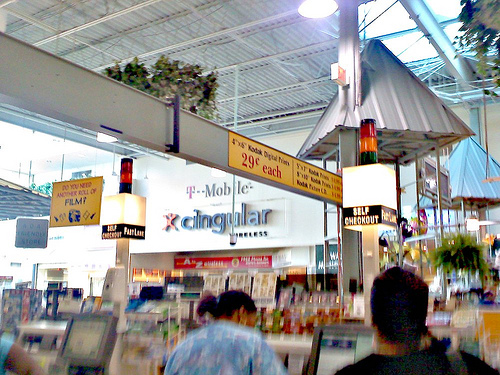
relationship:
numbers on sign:
[239, 153, 287, 185] [221, 122, 347, 202]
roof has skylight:
[3, 4, 500, 114] [356, 0, 500, 92]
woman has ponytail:
[162, 285, 283, 372] [197, 288, 221, 321]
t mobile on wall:
[183, 177, 249, 204] [150, 174, 351, 251]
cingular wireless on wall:
[183, 202, 297, 240] [150, 174, 351, 251]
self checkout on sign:
[340, 205, 391, 224] [342, 190, 399, 227]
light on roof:
[294, 0, 339, 29] [0, 0, 500, 162]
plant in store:
[431, 226, 494, 274] [375, 130, 496, 374]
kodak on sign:
[248, 145, 268, 153] [221, 122, 347, 202]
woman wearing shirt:
[162, 285, 283, 372] [165, 326, 291, 372]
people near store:
[158, 263, 496, 365] [375, 130, 496, 374]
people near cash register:
[158, 263, 496, 365] [59, 306, 115, 356]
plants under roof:
[109, 54, 224, 119] [3, 4, 500, 114]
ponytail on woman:
[197, 288, 221, 321] [162, 285, 283, 372]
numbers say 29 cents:
[239, 153, 287, 185] [245, 153, 262, 167]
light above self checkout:
[344, 166, 397, 201] [340, 205, 391, 224]